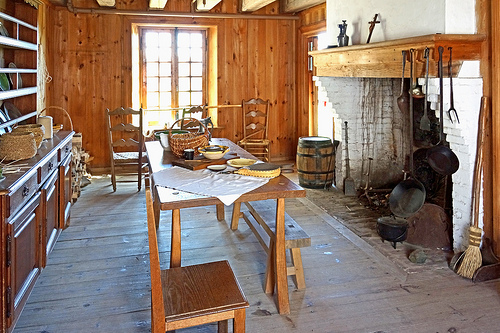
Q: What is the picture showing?
A: A kitchen.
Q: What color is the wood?
A: Natural.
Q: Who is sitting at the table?
A: No one.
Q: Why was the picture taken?
A: To capture the kitchen.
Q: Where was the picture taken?
A: In a kitchen.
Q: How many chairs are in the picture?
A: Three.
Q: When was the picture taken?
A: During the day.